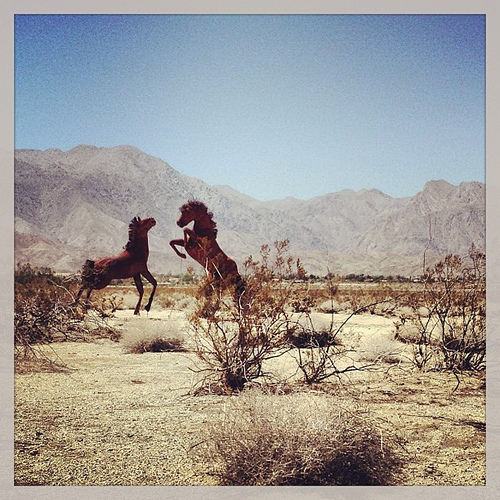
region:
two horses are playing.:
[77, 192, 244, 312]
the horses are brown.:
[71, 191, 249, 316]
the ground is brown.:
[15, 266, 490, 487]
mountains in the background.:
[15, 127, 487, 283]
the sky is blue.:
[12, 12, 487, 197]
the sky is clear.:
[12, 12, 488, 194]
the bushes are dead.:
[180, 272, 348, 387]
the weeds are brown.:
[185, 386, 407, 483]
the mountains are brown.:
[8, 122, 487, 284]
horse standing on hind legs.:
[161, 194, 251, 312]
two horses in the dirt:
[65, 181, 279, 336]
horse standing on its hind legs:
[165, 194, 260, 325]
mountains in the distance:
[15, 129, 489, 276]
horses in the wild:
[14, 18, 486, 484]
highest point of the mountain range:
[114, 137, 140, 153]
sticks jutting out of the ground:
[278, 295, 391, 387]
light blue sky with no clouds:
[15, 15, 487, 201]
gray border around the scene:
[0, 0, 498, 495]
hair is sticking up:
[121, 210, 142, 222]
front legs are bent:
[165, 228, 203, 268]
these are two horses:
[99, 192, 282, 343]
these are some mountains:
[173, 167, 379, 292]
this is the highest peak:
[77, 159, 139, 177]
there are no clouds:
[170, 74, 224, 121]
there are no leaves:
[113, 293, 280, 373]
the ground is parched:
[104, 418, 161, 496]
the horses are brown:
[83, 247, 276, 282]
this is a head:
[78, 199, 180, 261]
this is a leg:
[121, 233, 188, 323]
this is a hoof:
[118, 299, 164, 323]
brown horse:
[167, 202, 244, 314]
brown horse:
[67, 186, 157, 304]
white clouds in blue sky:
[35, 56, 86, 130]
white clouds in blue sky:
[95, 42, 112, 64]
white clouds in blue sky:
[194, 53, 231, 117]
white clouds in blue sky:
[284, 105, 362, 126]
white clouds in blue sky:
[287, 161, 298, 183]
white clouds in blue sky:
[334, 75, 364, 139]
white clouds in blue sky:
[218, 158, 272, 208]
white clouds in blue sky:
[230, 32, 284, 103]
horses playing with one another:
[57, 207, 253, 314]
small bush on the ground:
[200, 380, 391, 471]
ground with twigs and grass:
[20, 318, 475, 469]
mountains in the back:
[23, 127, 475, 273]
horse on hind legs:
[171, 200, 239, 288]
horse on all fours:
[68, 208, 161, 305]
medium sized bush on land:
[201, 236, 343, 376]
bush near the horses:
[6, 248, 121, 361]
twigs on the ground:
[358, 340, 445, 386]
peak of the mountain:
[23, 125, 183, 175]